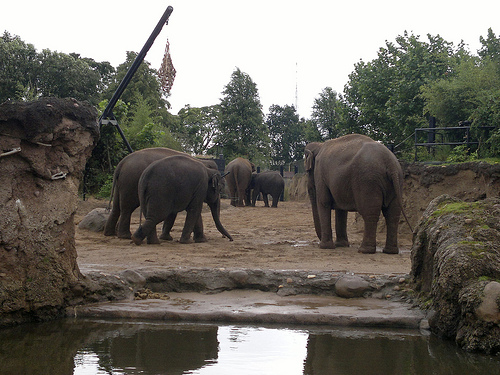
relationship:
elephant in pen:
[299, 131, 407, 255] [0, 123, 500, 372]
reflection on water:
[71, 324, 311, 373] [0, 318, 499, 374]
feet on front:
[318, 224, 352, 252] [303, 137, 348, 247]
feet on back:
[359, 229, 401, 256] [346, 136, 405, 253]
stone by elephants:
[78, 203, 109, 231] [104, 145, 235, 248]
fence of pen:
[410, 123, 497, 164] [0, 123, 500, 372]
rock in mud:
[333, 272, 371, 298] [83, 239, 417, 298]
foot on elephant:
[320, 232, 336, 251] [299, 131, 407, 255]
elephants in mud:
[104, 145, 235, 248] [83, 239, 417, 298]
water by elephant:
[0, 318, 499, 374] [299, 131, 407, 255]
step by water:
[77, 294, 420, 329] [0, 318, 499, 374]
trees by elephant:
[3, 29, 498, 165] [299, 131, 407, 255]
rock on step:
[333, 272, 371, 298] [77, 294, 420, 329]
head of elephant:
[296, 140, 319, 242] [299, 131, 407, 255]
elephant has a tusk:
[299, 131, 407, 255] [306, 178, 318, 218]